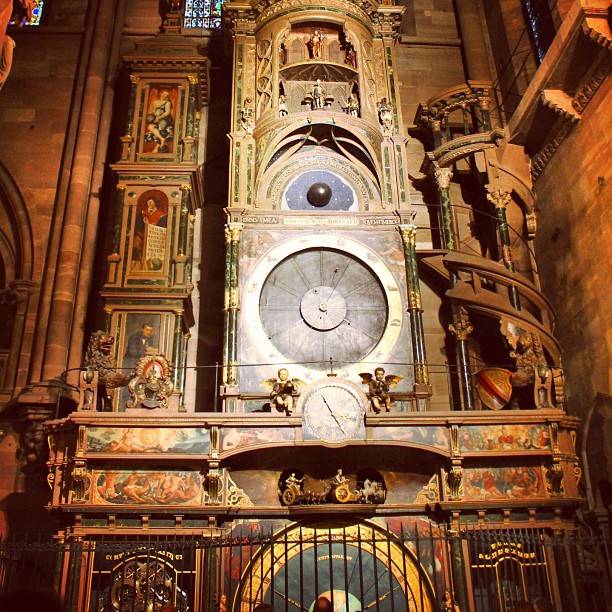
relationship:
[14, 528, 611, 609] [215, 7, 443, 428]
railing in front of tower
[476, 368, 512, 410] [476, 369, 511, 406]
sash with sash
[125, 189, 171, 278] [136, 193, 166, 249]
painting of man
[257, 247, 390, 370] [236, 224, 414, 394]
face of clock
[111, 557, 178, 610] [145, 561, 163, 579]
machine with gear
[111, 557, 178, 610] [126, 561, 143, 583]
machine with gear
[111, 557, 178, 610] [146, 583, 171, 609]
machine with gear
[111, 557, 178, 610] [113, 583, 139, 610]
machine with gear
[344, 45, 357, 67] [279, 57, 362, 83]
figurine on shelf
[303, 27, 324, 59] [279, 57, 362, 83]
figurine on shelf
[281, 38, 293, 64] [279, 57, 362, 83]
figurine on shelf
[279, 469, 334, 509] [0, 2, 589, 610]
decoration on wall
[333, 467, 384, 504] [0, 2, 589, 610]
decoration on wall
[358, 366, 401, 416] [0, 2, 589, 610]
decoration on wall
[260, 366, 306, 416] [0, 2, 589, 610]
decoration on wall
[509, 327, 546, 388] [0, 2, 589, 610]
decoration on wall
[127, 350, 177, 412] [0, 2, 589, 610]
decoration on wall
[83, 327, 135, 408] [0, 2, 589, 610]
decoration on wall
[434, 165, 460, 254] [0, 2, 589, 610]
decoration on wall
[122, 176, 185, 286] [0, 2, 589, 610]
decoration on wall